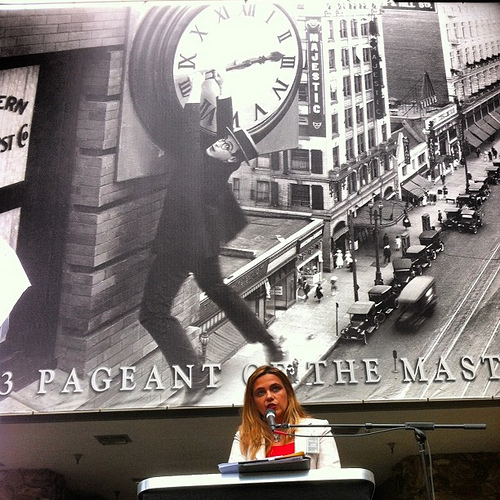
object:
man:
[139, 71, 287, 406]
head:
[206, 134, 245, 163]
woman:
[228, 365, 342, 470]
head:
[253, 373, 288, 418]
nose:
[266, 389, 274, 401]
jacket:
[228, 417, 342, 469]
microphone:
[264, 408, 276, 432]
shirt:
[266, 442, 294, 457]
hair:
[237, 365, 314, 459]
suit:
[138, 96, 275, 383]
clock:
[128, 1, 302, 162]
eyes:
[258, 391, 263, 395]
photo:
[1, 0, 500, 500]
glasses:
[218, 138, 234, 156]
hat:
[226, 126, 259, 166]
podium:
[135, 467, 375, 500]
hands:
[205, 51, 285, 80]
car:
[394, 275, 438, 334]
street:
[196, 135, 500, 406]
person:
[438, 210, 443, 223]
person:
[314, 283, 323, 302]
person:
[303, 278, 310, 299]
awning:
[464, 106, 500, 148]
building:
[384, 3, 500, 152]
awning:
[402, 174, 433, 200]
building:
[388, 118, 433, 206]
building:
[386, 97, 463, 183]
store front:
[429, 108, 461, 174]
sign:
[305, 16, 326, 138]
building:
[228, 3, 402, 223]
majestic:
[309, 33, 321, 114]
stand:
[278, 420, 488, 499]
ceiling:
[0, 408, 499, 499]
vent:
[94, 433, 132, 445]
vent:
[331, 427, 361, 435]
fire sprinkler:
[74, 454, 83, 464]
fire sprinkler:
[115, 490, 121, 499]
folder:
[238, 457, 311, 473]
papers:
[217, 463, 239, 474]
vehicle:
[340, 301, 379, 345]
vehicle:
[368, 285, 400, 324]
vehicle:
[392, 258, 415, 288]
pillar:
[376, 451, 499, 499]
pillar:
[0, 467, 66, 499]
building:
[3, 3, 195, 408]